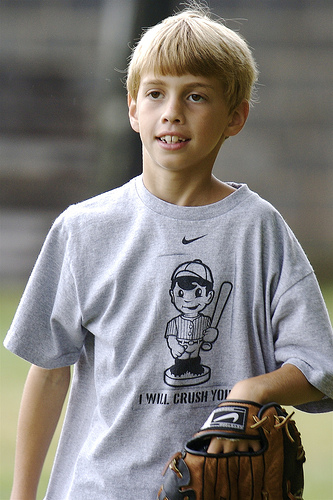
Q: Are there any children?
A: Yes, there is a child.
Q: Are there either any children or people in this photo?
A: Yes, there is a child.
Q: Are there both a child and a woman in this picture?
A: No, there is a child but no women.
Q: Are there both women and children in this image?
A: No, there is a child but no women.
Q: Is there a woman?
A: No, there are no women.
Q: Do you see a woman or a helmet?
A: No, there are no women or helmets.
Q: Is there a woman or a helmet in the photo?
A: No, there are no women or helmets.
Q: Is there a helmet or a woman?
A: No, there are no women or helmets.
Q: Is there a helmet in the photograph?
A: No, there are no helmets.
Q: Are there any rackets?
A: No, there are no rackets.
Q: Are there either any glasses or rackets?
A: No, there are no rackets or glasses.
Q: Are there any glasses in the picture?
A: No, there are no glasses.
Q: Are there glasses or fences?
A: No, there are no glasses or fences.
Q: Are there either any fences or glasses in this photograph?
A: No, there are no glasses or fences.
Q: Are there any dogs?
A: No, there are no dogs.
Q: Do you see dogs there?
A: No, there are no dogs.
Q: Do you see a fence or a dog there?
A: No, there are no dogs or fences.